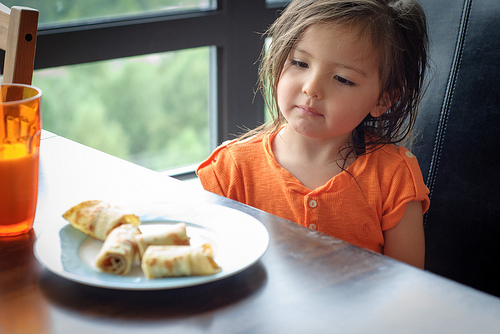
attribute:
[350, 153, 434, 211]
sleeve — short sleeve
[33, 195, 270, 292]
plate — young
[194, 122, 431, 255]
shirt — orange, short sleeve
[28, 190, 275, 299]
plate — white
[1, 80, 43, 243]
glass — orange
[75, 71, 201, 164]
tree — green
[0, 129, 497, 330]
table — Dinner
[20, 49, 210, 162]
landscape — blurred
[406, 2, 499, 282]
booth — black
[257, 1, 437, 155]
hair — on side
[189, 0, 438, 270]
girl — young, trying to decide